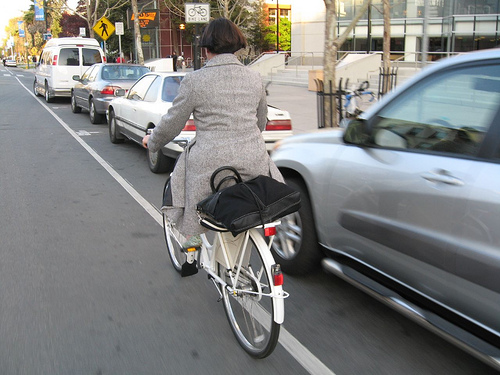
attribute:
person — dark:
[140, 18, 283, 277]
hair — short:
[199, 16, 247, 55]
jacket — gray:
[147, 53, 287, 235]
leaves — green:
[258, 17, 295, 51]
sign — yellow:
[88, 16, 113, 42]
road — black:
[51, 240, 157, 341]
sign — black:
[83, 13, 123, 49]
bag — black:
[195, 164, 302, 236]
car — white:
[103, 69, 297, 178]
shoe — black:
[181, 262, 198, 277]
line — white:
[8, 64, 341, 374]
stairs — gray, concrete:
[280, 55, 348, 106]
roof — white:
[292, 17, 328, 27]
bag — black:
[187, 160, 299, 234]